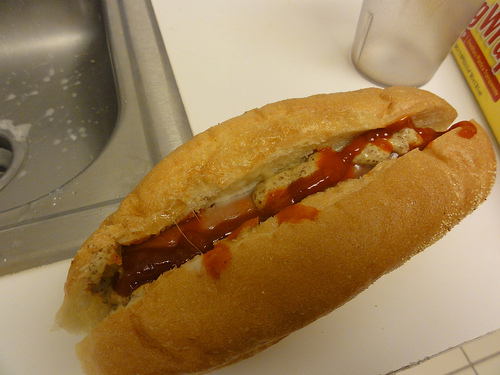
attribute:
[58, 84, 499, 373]
hot dog — long, uneaten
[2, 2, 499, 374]
counter — white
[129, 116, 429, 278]
sauce — red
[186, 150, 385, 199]
mustard — yellow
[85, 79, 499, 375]
bun — golden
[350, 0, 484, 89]
cup — nearby, plastic, empty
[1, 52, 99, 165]
bubbles — white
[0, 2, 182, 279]
sink — silver, stainless steel, steel, empty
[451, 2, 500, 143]
box — yellow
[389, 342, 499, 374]
tile — white